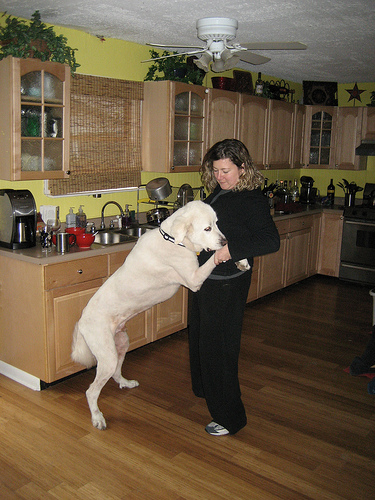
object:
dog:
[71, 198, 251, 431]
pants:
[187, 288, 247, 434]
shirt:
[197, 187, 280, 281]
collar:
[156, 225, 186, 248]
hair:
[198, 137, 267, 194]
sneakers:
[204, 421, 231, 435]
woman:
[187, 138, 281, 436]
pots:
[144, 175, 170, 203]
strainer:
[145, 207, 169, 227]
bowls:
[73, 229, 93, 251]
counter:
[0, 215, 138, 267]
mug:
[37, 226, 53, 249]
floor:
[0, 274, 374, 499]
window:
[69, 74, 145, 191]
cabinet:
[18, 57, 65, 172]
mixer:
[298, 174, 318, 203]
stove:
[340, 207, 375, 282]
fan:
[139, 15, 308, 75]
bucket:
[176, 181, 193, 205]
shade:
[71, 93, 127, 172]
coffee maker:
[54, 231, 72, 254]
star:
[343, 83, 368, 105]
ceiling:
[0, 0, 374, 90]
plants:
[0, 9, 81, 81]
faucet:
[100, 199, 125, 229]